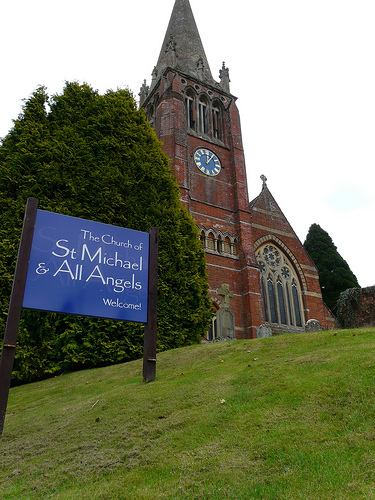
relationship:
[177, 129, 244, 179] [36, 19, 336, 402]
clock on building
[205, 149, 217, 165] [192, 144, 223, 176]
hands of clock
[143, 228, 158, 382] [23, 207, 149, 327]
wooden post for sign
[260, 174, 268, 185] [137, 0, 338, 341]
cross on building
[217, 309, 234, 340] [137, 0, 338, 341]
tombstone in front of building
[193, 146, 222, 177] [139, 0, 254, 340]
clock on tower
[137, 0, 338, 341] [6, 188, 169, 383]
building on poles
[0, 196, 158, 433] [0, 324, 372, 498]
sign on grass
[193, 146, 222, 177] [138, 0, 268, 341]
clock in tower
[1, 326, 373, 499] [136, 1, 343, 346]
hill in front of church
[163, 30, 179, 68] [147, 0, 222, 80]
statue at roof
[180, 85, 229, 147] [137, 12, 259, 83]
arches in tower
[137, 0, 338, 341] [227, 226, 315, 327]
building has window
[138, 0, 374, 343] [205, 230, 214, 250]
building has window